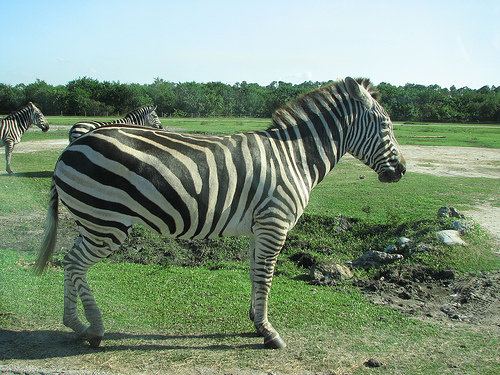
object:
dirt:
[364, 264, 499, 327]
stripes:
[61, 148, 177, 237]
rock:
[345, 250, 404, 269]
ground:
[0, 116, 500, 375]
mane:
[272, 77, 377, 127]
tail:
[31, 180, 59, 280]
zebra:
[34, 77, 408, 351]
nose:
[393, 159, 407, 174]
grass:
[0, 115, 500, 375]